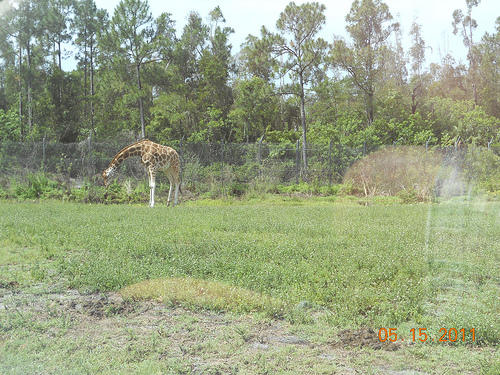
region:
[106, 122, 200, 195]
Tall giraffe bending over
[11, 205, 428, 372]
trimmed green grass on field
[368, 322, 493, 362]
Date of photo taken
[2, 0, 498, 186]
Tall green trees behind giraffe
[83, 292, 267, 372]
Dirt patches in fields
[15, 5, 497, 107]
Blue sky shining through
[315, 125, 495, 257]
Reflection of leg on window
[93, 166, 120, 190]
Head of tall giraffe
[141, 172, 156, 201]
Front legs of tall giraffe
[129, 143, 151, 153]
Brown and white spots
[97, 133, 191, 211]
giraffe grazing in field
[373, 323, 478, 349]
date stamp on photo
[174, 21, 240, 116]
green leaves on trees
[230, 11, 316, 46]
clear blue sky behind tree line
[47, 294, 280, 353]
patch of bare dirt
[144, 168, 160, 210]
long front legs of giraffe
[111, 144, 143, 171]
neck craned down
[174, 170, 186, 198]
tail with black hair on tip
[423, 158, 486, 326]
reflection of photographer in window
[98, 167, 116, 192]
head of giraffe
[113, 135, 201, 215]
the giraffe is standing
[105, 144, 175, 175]
the neck is long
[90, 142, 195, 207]
neck on the giraffe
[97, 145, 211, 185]
the neck is bent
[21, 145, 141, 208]
shrubs by the fence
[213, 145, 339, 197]
the fence is wire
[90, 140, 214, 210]
giraffe by the bushes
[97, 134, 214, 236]
giraffe in the grass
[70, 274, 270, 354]
dirt in the grass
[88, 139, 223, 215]
the giraffe is spotted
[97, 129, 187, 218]
giraffe with bent neck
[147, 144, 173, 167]
brown spots on giraffe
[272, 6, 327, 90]
tree with green leaves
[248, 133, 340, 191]
metal fence of enclosure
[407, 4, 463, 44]
light blue daytime sky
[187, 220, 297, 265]
tall grass in enclosure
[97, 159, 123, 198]
head bent forward toward grass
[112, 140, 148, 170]
bent neck of giraffe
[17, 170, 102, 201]
weeds in front of fence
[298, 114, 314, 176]
thin trunk of tree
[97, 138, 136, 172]
Giraffe has long neck.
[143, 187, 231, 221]
Giraffe has white legs.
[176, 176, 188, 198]
Giraffe has dark hair on the tip of tail.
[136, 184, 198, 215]
Giraffe is standing in a grassy field.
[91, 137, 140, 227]
Giraffe is bending down to eat.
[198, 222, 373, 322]
Grass is green in area.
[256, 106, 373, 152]
Green leaves on trees.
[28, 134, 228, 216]
Giraffe is standing near fence.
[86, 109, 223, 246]
Giraffe is brown and white.